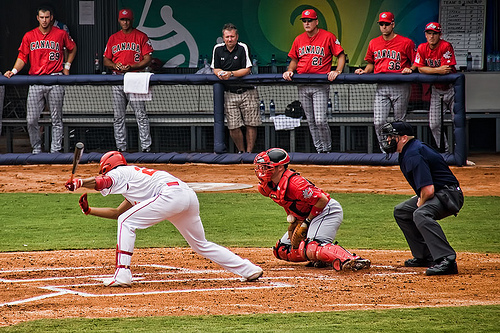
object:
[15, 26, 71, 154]
uniform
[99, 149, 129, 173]
head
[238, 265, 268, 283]
feet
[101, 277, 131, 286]
feet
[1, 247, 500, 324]
sand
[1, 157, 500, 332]
baseball field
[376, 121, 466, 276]
umpire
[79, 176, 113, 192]
arm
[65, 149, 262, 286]
man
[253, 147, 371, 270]
person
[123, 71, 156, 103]
towel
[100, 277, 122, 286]
foot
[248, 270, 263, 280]
foot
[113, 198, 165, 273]
leg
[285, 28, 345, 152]
uniform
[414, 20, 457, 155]
man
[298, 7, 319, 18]
cap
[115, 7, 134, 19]
cap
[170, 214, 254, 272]
leg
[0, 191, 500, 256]
grass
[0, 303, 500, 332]
grass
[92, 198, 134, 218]
arm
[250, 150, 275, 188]
mask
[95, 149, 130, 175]
helmet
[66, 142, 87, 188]
bat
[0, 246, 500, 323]
dirt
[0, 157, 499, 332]
ground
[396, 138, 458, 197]
shirt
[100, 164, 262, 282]
uniform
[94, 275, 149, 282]
base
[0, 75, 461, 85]
rail